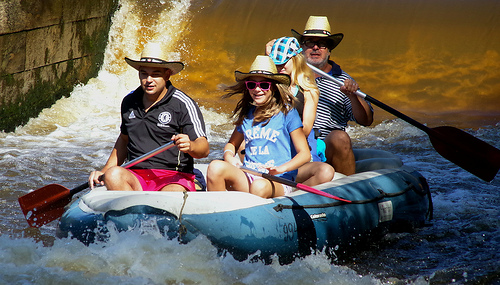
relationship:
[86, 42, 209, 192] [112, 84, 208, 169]
he wearing shirt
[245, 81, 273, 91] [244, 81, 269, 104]
glasses on face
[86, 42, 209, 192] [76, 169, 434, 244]
he on raft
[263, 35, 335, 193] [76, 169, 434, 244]
girl on raft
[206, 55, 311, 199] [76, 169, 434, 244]
girl on raft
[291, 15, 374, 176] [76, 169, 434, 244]
man on raft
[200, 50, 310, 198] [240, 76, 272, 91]
girl in glasses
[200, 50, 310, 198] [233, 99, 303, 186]
girl in shirt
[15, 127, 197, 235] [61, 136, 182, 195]
paddle with handle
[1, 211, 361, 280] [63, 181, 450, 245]
water splashing in front of raft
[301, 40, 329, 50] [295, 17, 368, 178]
black sunglasses on man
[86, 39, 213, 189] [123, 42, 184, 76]
he wearing cowboy hat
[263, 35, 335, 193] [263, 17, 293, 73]
girl wearing helmet.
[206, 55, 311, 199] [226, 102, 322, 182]
girl has on a blue shirt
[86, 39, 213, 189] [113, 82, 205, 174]
he has on a blue black shirt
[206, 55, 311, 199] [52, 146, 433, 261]
girl riding raft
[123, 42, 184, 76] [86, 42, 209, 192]
cowboy hat on he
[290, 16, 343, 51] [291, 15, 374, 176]
cowboy hat on man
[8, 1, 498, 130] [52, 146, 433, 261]
brown water behind raft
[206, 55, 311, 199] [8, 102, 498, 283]
girl in water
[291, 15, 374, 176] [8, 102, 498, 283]
man in water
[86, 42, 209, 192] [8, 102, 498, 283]
he in water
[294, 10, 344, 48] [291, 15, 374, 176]
cowboy hat on man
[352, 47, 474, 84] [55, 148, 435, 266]
water behind boat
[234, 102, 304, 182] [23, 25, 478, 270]
shirt on rafter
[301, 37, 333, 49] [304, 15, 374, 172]
black sunglasses on man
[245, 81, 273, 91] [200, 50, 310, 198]
glasses on girl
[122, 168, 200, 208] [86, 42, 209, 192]
shorts on he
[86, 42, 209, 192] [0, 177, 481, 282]
he doing water rafting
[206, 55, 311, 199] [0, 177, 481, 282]
girl doing water rafting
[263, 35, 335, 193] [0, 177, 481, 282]
girl doing water rafting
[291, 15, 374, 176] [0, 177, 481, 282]
man doing water rafting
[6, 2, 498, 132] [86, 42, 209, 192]
waterfall behind he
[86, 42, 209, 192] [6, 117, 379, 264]
he holding paddles